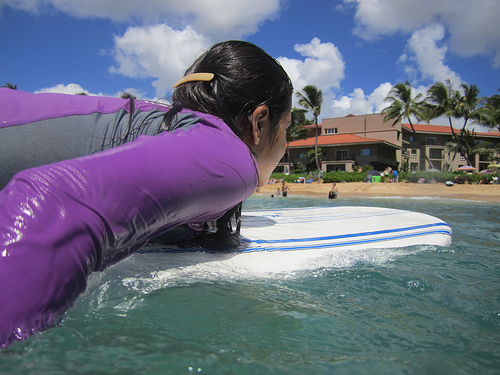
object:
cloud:
[294, 37, 346, 94]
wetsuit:
[2, 73, 262, 373]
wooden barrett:
[172, 71, 218, 92]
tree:
[381, 81, 447, 170]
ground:
[266, 173, 499, 198]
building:
[262, 109, 497, 185]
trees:
[424, 74, 479, 172]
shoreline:
[337, 190, 497, 203]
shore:
[258, 176, 496, 215]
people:
[326, 182, 339, 199]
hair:
[146, 36, 298, 253]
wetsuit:
[0, 85, 260, 345]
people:
[389, 169, 398, 183]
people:
[384, 167, 389, 183]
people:
[317, 178, 323, 184]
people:
[464, 175, 470, 184]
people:
[478, 175, 484, 185]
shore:
[247, 172, 494, 208]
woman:
[0, 39, 293, 349]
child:
[275, 188, 281, 197]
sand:
[254, 179, 498, 200]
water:
[1, 194, 493, 372]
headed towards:
[145, 17, 480, 247]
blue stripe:
[244, 223, 452, 243]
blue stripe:
[224, 230, 452, 252]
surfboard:
[43, 201, 453, 288]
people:
[280, 180, 292, 197]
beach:
[261, 180, 500, 204]